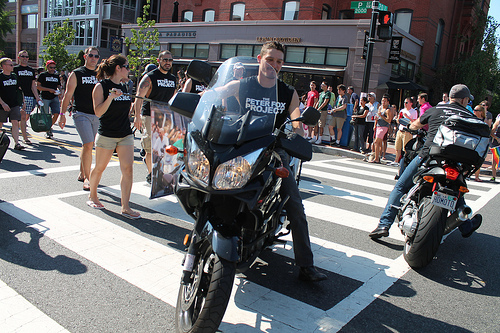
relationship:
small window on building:
[164, 58, 277, 144] [132, 10, 464, 128]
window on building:
[293, 31, 357, 71] [150, 10, 485, 132]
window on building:
[178, 8, 198, 22] [132, 10, 464, 128]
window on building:
[393, 6, 413, 33] [161, 0, 488, 104]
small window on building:
[427, 16, 446, 70] [161, 0, 488, 104]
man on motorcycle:
[197, 33, 330, 281] [166, 40, 331, 326]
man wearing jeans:
[368, 80, 485, 246] [384, 155, 469, 237]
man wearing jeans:
[248, 33, 336, 135] [244, 181, 356, 269]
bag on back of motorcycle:
[429, 107, 493, 170] [394, 123, 461, 274]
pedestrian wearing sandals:
[86, 53, 141, 221] [81, 181, 232, 243]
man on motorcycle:
[197, 33, 330, 281] [165, 55, 320, 331]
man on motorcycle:
[368, 80, 485, 246] [391, 115, 473, 267]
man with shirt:
[197, 33, 330, 281] [236, 73, 294, 138]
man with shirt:
[368, 80, 485, 246] [415, 100, 476, 159]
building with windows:
[38, 0, 140, 68] [42, 8, 104, 40]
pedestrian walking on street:
[86, 53, 141, 221] [11, 111, 498, 287]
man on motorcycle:
[197, 33, 330, 281] [163, 130, 295, 330]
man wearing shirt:
[197, 33, 330, 281] [248, 89, 276, 110]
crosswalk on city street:
[2, 155, 499, 330] [7, 95, 498, 332]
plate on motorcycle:
[432, 187, 464, 212] [159, 77, 293, 324]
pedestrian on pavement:
[59, 47, 109, 191] [22, 144, 182, 315]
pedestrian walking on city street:
[59, 47, 109, 191] [7, 95, 498, 332]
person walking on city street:
[12, 49, 44, 144] [7, 95, 498, 332]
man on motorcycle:
[197, 33, 330, 281] [151, 54, 321, 328]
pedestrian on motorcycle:
[86, 53, 141, 221] [175, 53, 315, 331]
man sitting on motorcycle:
[197, 33, 330, 281] [165, 55, 320, 331]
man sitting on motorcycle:
[368, 71, 485, 246] [356, 124, 480, 266]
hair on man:
[157, 49, 173, 61] [155, 49, 183, 96]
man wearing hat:
[368, 80, 485, 246] [441, 83, 476, 98]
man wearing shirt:
[415, 92, 432, 130] [419, 101, 429, 117]